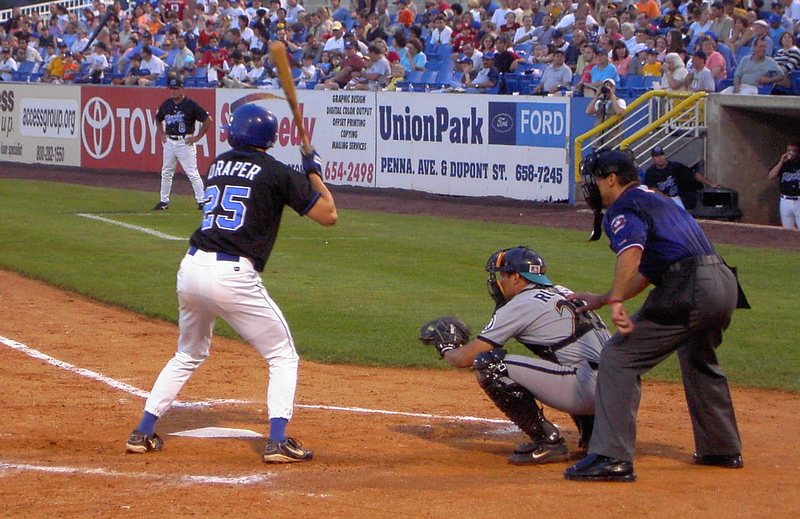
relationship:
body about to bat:
[126, 103, 336, 463] [267, 33, 312, 157]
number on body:
[199, 187, 259, 235] [126, 103, 336, 463]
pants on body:
[145, 247, 306, 418] [126, 103, 336, 463]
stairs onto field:
[575, 85, 706, 201] [0, 7, 797, 515]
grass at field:
[5, 181, 797, 397] [0, 7, 797, 515]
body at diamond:
[126, 103, 336, 463] [167, 426, 264, 437]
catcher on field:
[425, 248, 611, 474] [0, 7, 797, 515]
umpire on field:
[567, 152, 745, 475] [0, 7, 797, 515]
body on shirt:
[126, 103, 336, 463] [188, 146, 321, 266]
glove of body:
[300, 146, 326, 172] [126, 103, 336, 463]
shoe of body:
[266, 439, 314, 468] [126, 103, 336, 463]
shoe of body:
[124, 432, 162, 456] [126, 103, 336, 463]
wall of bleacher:
[0, 81, 614, 190] [371, 91, 567, 200]